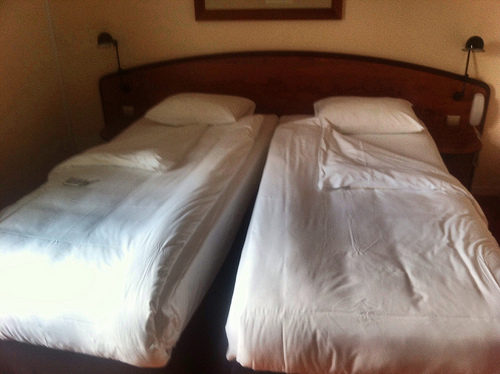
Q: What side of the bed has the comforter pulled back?
A: Right side.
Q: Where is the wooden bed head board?
A: At the top of the bed.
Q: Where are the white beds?
A: Next to each other.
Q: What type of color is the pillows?
A: White.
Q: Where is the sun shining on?
A: The bed.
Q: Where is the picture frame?
A: Above the bed.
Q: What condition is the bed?
A: Wrinkles.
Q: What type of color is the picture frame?
A: Brown.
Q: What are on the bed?
A: Pillows.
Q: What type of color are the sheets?
A: White.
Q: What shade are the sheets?
A: White.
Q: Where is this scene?
A: Hotel.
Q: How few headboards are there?
A: 1.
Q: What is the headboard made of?
A: Wooden.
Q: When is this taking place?
A: Afternoon.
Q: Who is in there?
A: Know one.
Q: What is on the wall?
A: Picture.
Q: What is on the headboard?
A: Lamps.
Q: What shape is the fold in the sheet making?
A: Triangle.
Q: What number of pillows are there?
A: 2.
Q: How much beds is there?
A: 2.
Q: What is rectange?
A: Beds.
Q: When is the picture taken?
A: Day time.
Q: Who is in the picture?
A: No one.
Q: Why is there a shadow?
A: Sunlight.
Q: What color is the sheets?
A: White.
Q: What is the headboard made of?
A: Wood.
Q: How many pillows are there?
A: Two.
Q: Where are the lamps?
A: On headboard.